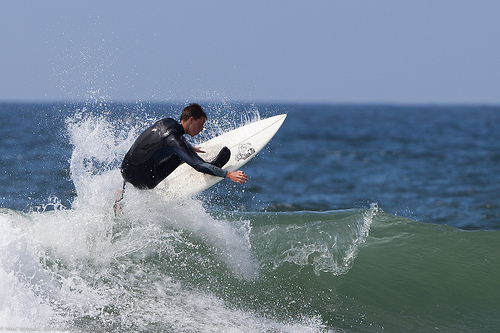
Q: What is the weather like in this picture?
A: It is clear.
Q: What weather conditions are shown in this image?
A: It is clear.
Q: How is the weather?
A: It is clear.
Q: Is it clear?
A: Yes, it is clear.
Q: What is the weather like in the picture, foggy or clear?
A: It is clear.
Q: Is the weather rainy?
A: No, it is clear.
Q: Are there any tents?
A: No, there are no tents.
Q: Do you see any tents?
A: No, there are no tents.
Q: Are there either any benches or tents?
A: No, there are no tents or benches.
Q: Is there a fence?
A: No, there are no fences.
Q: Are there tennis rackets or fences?
A: No, there are no fences or tennis rackets.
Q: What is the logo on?
A: The logo is on the surfboard.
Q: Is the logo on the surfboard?
A: Yes, the logo is on the surfboard.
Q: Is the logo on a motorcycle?
A: No, the logo is on the surfboard.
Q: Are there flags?
A: No, there are no flags.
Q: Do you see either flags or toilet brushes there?
A: No, there are no flags or toilet brushes.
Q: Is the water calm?
A: Yes, the water is calm.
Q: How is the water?
A: The water is calm.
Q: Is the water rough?
A: No, the water is calm.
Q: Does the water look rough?
A: No, the water is calm.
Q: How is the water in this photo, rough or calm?
A: The water is calm.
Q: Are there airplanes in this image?
A: No, there are no airplanes.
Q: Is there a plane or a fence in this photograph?
A: No, there are no airplanes or fences.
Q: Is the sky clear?
A: Yes, the sky is clear.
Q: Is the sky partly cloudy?
A: No, the sky is clear.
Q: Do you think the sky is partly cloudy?
A: No, the sky is clear.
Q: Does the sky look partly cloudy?
A: No, the sky is clear.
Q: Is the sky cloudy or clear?
A: The sky is clear.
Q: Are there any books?
A: No, there are no books.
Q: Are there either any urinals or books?
A: No, there are no books or urinals.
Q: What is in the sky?
A: The clouds are in the sky.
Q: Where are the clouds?
A: The clouds are in the sky.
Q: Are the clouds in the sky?
A: Yes, the clouds are in the sky.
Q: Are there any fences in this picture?
A: No, there are no fences.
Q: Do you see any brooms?
A: No, there are no brooms.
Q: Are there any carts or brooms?
A: No, there are no brooms or carts.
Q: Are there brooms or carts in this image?
A: No, there are no brooms or carts.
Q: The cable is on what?
A: The cable is on the surfboard.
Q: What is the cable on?
A: The cable is on the surfboard.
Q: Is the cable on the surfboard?
A: Yes, the cable is on the surfboard.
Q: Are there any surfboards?
A: Yes, there is a surfboard.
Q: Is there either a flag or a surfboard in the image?
A: Yes, there is a surfboard.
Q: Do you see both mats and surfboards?
A: No, there is a surfboard but no mats.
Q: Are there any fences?
A: No, there are no fences.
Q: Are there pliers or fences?
A: No, there are no fences or pliers.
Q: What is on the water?
A: The surfboard is on the water.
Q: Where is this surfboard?
A: The surfboard is on the water.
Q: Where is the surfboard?
A: The surfboard is on the water.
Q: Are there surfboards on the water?
A: Yes, there is a surfboard on the water.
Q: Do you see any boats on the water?
A: No, there is a surfboard on the water.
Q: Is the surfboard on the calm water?
A: Yes, the surfboard is on the water.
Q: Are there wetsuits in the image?
A: Yes, there is a wetsuit.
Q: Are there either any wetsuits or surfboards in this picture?
A: Yes, there is a wetsuit.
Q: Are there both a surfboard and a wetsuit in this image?
A: Yes, there are both a wetsuit and a surfboard.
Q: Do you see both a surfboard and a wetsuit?
A: Yes, there are both a wetsuit and a surfboard.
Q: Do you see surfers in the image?
A: Yes, there is a surfer.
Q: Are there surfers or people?
A: Yes, there is a surfer.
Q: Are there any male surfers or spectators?
A: Yes, there is a male surfer.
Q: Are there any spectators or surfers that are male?
A: Yes, the surfer is male.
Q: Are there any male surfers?
A: Yes, there is a male surfer.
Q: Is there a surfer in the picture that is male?
A: Yes, there is a surfer that is male.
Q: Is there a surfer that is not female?
A: Yes, there is a male surfer.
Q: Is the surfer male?
A: Yes, the surfer is male.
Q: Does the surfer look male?
A: Yes, the surfer is male.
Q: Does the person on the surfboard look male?
A: Yes, the surfer is male.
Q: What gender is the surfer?
A: The surfer is male.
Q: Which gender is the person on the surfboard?
A: The surfer is male.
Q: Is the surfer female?
A: No, the surfer is male.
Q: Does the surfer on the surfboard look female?
A: No, the surfer is male.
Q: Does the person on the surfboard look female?
A: No, the surfer is male.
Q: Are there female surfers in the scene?
A: No, there is a surfer but he is male.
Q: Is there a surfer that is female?
A: No, there is a surfer but he is male.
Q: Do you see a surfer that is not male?
A: No, there is a surfer but he is male.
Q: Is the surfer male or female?
A: The surfer is male.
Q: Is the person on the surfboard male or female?
A: The surfer is male.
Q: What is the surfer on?
A: The surfer is on the surf board.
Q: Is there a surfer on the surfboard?
A: Yes, there is a surfer on the surfboard.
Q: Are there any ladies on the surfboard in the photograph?
A: No, there is a surfer on the surfboard.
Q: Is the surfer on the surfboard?
A: Yes, the surfer is on the surfboard.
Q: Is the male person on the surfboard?
A: Yes, the surfer is on the surfboard.